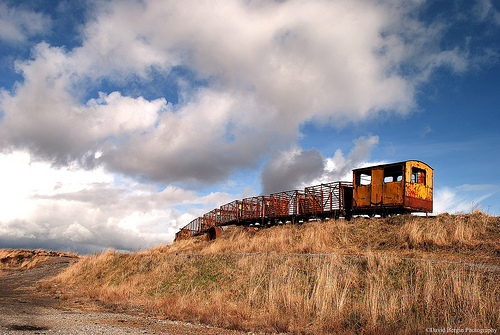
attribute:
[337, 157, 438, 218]
train car — yellow, abandoned, brown, taking a curve, rusting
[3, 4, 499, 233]
sky — cloudy, blue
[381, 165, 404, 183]
window — medium sized, open, without glass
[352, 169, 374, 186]
window — medium sized, open, without glass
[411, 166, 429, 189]
window — at rear, open, without glass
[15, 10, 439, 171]
cloud — gray, large, white, bright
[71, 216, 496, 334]
field — grassy, yellow, green, brown, dead, dry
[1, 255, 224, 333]
road — gray, gravel, rocky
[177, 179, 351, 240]
train cars — mesh, red, large, empty, very long, plywood, wood, like cages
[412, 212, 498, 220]
tracks — for trains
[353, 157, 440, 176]
roof — curved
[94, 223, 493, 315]
hill — small